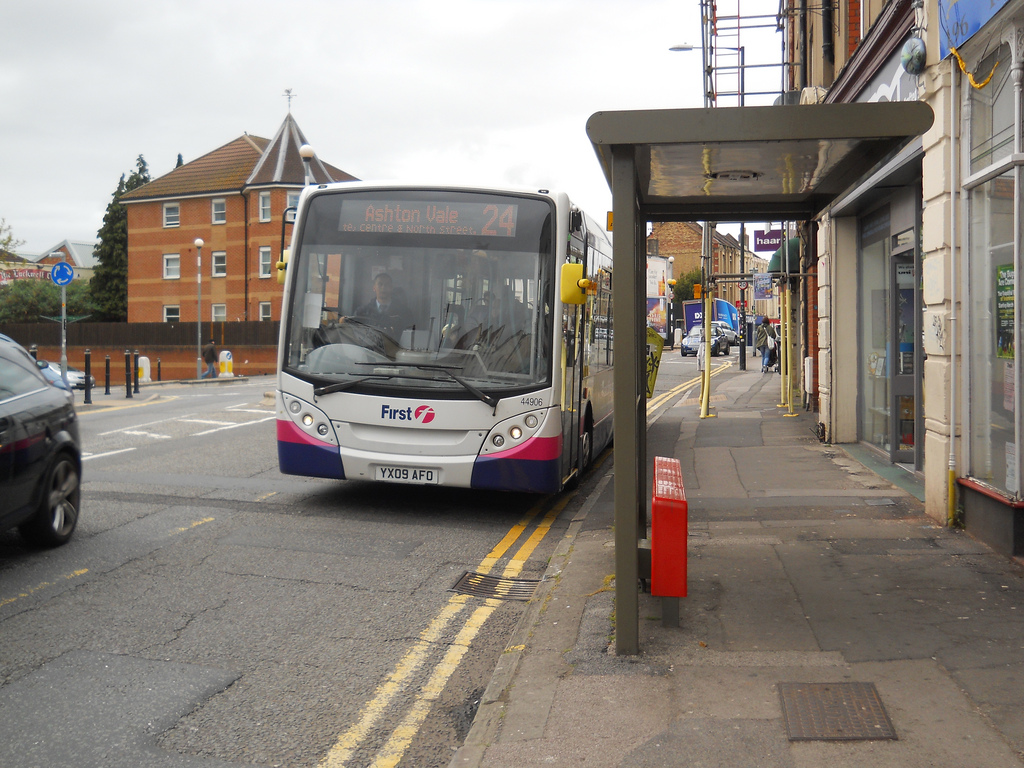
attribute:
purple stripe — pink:
[270, 441, 553, 486]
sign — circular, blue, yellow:
[45, 242, 88, 291]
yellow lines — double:
[257, 355, 744, 766]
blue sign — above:
[935, 0, 1021, 84]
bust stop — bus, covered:
[585, 87, 949, 657]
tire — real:
[29, 447, 100, 549]